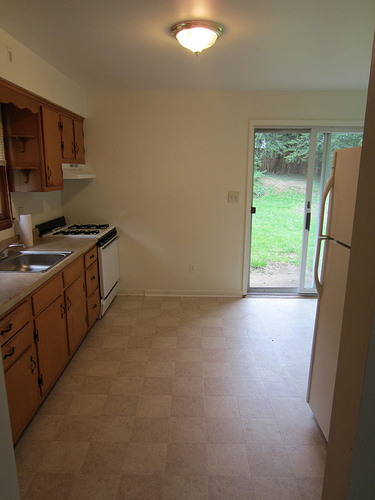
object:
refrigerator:
[305, 145, 367, 443]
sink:
[1, 248, 73, 273]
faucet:
[2, 243, 27, 257]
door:
[33, 297, 76, 389]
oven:
[38, 219, 121, 314]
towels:
[19, 215, 34, 249]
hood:
[61, 161, 97, 178]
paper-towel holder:
[17, 204, 33, 246]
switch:
[226, 184, 239, 202]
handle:
[59, 303, 67, 317]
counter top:
[72, 234, 96, 244]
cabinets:
[74, 113, 84, 167]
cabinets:
[3, 339, 42, 447]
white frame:
[242, 118, 255, 294]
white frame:
[247, 119, 365, 127]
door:
[249, 125, 319, 290]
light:
[171, 19, 223, 57]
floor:
[115, 285, 275, 485]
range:
[34, 214, 121, 316]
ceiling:
[4, 0, 362, 94]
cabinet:
[34, 294, 70, 402]